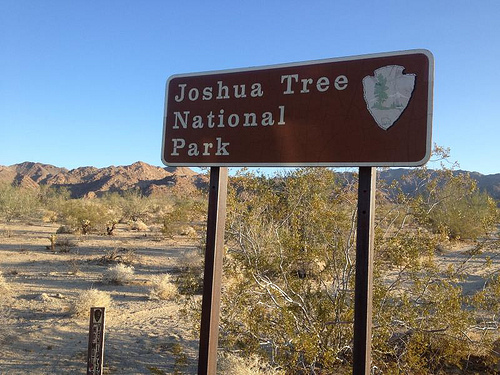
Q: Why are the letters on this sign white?
A: Design.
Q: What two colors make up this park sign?
A: Brown and white.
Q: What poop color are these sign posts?
A: Brown.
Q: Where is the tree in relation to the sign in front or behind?
A: Behind.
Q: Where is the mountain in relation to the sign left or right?
A: Left.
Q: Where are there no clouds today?
A: Sky.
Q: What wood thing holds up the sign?
A: Post.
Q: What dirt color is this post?
A: Brown.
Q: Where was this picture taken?
A: Joshua Tree National Park.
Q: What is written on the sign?
A: Joshua Tree National Park.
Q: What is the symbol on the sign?
A: Arrowhead.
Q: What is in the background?
A: Mountains.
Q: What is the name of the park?
A: Joshua tree national park.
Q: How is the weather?
A: Clear.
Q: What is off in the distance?
A: Hills.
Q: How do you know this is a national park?
A: The sign.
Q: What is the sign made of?
A: Metal.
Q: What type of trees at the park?
A: Joshua.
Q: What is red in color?
A: The sign.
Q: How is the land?
A: Dry.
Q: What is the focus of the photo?
A: The sign.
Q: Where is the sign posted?
A: Desert.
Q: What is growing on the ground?
A: Trees.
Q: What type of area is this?
A: Desert.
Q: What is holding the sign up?
A: Two pole.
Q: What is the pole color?
A: Brown.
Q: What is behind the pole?
A: Shrubs.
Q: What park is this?
A: Joshua Tree.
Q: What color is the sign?
A: Brown.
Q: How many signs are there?
A: One.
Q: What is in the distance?
A: Hills.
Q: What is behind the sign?
A: Tree.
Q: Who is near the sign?
A: No one.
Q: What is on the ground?
A: Dirt.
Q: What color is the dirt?
A: Tan.